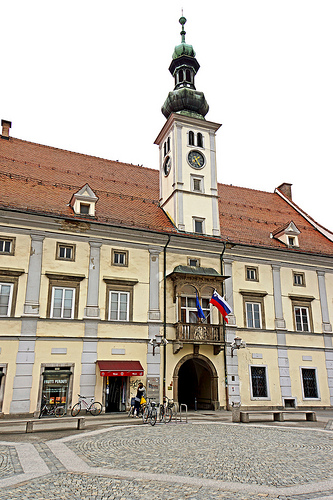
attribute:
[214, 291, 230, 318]
flag — red, blue, white, flying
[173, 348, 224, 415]
doorway — arched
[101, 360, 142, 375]
awning — red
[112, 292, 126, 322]
window — closed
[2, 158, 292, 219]
roof — brown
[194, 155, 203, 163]
hands — yellow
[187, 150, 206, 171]
clock — round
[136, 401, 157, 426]
bike — riderless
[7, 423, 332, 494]
road — interesting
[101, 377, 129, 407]
door — open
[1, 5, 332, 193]
sky — hazy, blue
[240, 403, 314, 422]
bench — long, empty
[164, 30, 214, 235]
tower — top, tan, clock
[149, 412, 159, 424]
wheel — round, black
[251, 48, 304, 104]
clouds — white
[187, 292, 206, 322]
flag — blue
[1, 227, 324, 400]
wall — yellow